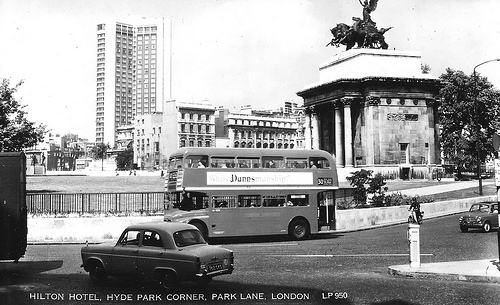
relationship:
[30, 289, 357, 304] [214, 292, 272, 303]
words say park lane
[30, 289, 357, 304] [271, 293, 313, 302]
words say london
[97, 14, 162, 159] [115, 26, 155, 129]
building has windows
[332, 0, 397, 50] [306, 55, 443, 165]
statue on top of building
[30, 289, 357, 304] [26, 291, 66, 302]
words say hilton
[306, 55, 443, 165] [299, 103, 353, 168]
building has pillars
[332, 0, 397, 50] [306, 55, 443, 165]
statue on building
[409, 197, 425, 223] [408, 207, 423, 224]
person riding bike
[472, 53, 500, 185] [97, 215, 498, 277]
post near road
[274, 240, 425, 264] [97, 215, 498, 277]
line on road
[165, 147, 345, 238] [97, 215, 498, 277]
bus on road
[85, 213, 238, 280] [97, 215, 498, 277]
car on road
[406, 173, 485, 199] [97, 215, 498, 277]
sidewalk beside road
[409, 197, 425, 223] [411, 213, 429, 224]
person on bike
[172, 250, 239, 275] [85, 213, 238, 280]
back of car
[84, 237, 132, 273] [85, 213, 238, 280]
front of car